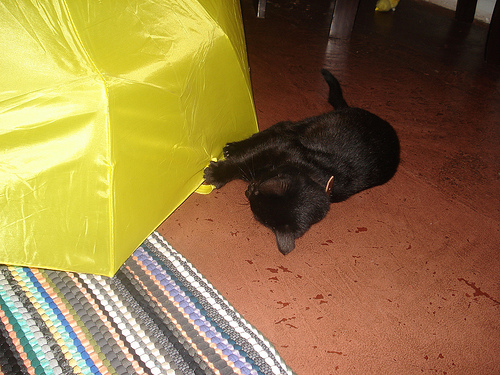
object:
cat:
[197, 64, 402, 258]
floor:
[262, 260, 489, 322]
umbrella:
[0, 0, 266, 279]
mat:
[0, 225, 301, 374]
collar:
[308, 163, 338, 198]